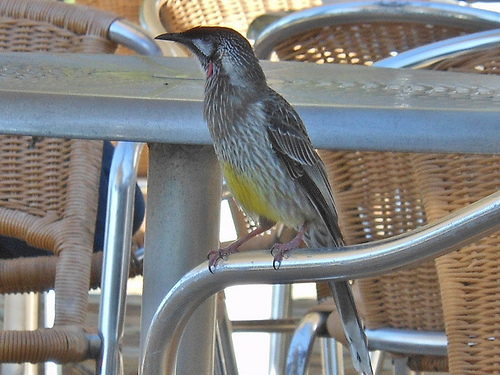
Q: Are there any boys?
A: No, there are no boys.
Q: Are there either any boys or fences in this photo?
A: No, there are no boys or fences.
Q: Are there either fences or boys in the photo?
A: No, there are no boys or fences.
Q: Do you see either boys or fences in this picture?
A: No, there are no fences or boys.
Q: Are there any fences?
A: No, there are no fences.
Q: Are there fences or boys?
A: No, there are no fences or boys.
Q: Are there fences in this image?
A: No, there are no fences.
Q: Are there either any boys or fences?
A: No, there are no fences or boys.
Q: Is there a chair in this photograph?
A: Yes, there is a chair.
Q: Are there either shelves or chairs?
A: Yes, there is a chair.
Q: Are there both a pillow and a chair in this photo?
A: No, there is a chair but no pillows.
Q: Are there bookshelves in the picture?
A: No, there are no bookshelves.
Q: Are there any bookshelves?
A: No, there are no bookshelves.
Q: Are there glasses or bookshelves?
A: No, there are no bookshelves or glasses.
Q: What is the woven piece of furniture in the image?
A: The piece of furniture is a chair.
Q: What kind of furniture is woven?
A: The furniture is a chair.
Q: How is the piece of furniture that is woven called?
A: The piece of furniture is a chair.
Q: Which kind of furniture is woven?
A: The furniture is a chair.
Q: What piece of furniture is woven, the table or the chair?
A: The chair is woven.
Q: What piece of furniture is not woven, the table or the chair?
A: The table is not woven.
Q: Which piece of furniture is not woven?
A: The piece of furniture is a table.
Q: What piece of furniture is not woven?
A: The piece of furniture is a table.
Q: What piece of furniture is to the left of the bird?
A: The piece of furniture is a chair.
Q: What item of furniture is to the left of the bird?
A: The piece of furniture is a chair.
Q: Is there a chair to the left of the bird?
A: Yes, there is a chair to the left of the bird.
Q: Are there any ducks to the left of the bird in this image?
A: No, there is a chair to the left of the bird.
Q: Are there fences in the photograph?
A: No, there are no fences.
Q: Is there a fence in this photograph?
A: No, there are no fences.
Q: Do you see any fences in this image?
A: No, there are no fences.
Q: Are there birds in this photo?
A: Yes, there is a bird.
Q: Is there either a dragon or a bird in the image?
A: Yes, there is a bird.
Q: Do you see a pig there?
A: No, there are no pigs.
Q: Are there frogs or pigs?
A: No, there are no pigs or frogs.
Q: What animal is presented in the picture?
A: The animal is a bird.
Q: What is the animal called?
A: The animal is a bird.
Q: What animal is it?
A: The animal is a bird.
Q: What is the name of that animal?
A: This is a bird.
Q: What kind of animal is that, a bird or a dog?
A: This is a bird.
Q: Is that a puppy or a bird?
A: That is a bird.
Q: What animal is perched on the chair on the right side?
A: The bird is perched on the chair.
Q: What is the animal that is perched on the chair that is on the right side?
A: The animal is a bird.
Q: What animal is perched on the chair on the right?
A: The animal is a bird.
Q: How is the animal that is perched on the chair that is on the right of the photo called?
A: The animal is a bird.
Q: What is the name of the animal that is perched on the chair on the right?
A: The animal is a bird.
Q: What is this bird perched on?
A: The bird is perched on the chair.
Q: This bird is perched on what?
A: The bird is perched on the chair.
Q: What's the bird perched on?
A: The bird is perched on the chair.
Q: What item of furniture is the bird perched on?
A: The bird is perched on the chair.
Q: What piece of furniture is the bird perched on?
A: The bird is perched on the chair.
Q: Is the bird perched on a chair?
A: Yes, the bird is perched on a chair.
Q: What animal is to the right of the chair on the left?
A: The animal is a bird.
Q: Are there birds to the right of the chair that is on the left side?
A: Yes, there is a bird to the right of the chair.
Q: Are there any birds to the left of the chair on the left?
A: No, the bird is to the right of the chair.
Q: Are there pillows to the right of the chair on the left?
A: No, there is a bird to the right of the chair.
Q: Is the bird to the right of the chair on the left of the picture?
A: Yes, the bird is to the right of the chair.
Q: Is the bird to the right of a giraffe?
A: No, the bird is to the right of the chair.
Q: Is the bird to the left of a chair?
A: No, the bird is to the right of a chair.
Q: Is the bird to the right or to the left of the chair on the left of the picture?
A: The bird is to the right of the chair.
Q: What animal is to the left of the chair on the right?
A: The animal is a bird.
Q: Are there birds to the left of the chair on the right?
A: Yes, there is a bird to the left of the chair.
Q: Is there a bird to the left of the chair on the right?
A: Yes, there is a bird to the left of the chair.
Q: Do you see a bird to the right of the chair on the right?
A: No, the bird is to the left of the chair.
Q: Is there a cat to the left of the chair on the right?
A: No, there is a bird to the left of the chair.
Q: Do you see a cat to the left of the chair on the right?
A: No, there is a bird to the left of the chair.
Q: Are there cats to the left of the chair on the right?
A: No, there is a bird to the left of the chair.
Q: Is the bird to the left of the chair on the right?
A: Yes, the bird is to the left of the chair.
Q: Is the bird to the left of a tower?
A: No, the bird is to the left of the chair.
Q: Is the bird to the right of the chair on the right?
A: No, the bird is to the left of the chair.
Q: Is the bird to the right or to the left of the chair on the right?
A: The bird is to the left of the chair.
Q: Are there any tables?
A: Yes, there is a table.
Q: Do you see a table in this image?
A: Yes, there is a table.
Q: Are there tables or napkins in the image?
A: Yes, there is a table.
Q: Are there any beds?
A: No, there are no beds.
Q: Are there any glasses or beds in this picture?
A: No, there are no beds or glasses.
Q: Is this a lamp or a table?
A: This is a table.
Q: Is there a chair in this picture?
A: Yes, there is a chair.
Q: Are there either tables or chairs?
A: Yes, there is a chair.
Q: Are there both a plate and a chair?
A: No, there is a chair but no plates.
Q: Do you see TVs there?
A: No, there are no tvs.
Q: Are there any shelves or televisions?
A: No, there are no televisions or shelves.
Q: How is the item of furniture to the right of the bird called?
A: The piece of furniture is a chair.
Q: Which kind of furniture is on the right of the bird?
A: The piece of furniture is a chair.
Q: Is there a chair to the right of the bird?
A: Yes, there is a chair to the right of the bird.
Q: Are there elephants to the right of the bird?
A: No, there is a chair to the right of the bird.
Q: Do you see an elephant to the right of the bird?
A: No, there is a chair to the right of the bird.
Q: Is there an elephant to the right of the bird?
A: No, there is a chair to the right of the bird.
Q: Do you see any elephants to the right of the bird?
A: No, there is a chair to the right of the bird.